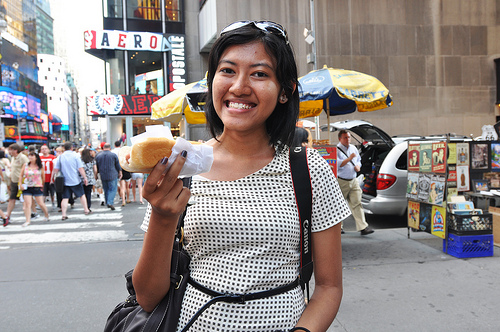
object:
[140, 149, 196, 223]
hand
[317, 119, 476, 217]
car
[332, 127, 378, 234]
man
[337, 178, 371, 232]
pants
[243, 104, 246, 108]
teeth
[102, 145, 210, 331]
purse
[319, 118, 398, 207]
hatchback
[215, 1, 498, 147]
wall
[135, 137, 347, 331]
dress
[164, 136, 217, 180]
paper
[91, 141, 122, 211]
people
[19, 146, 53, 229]
woman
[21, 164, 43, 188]
sleeveless top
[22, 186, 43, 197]
shorts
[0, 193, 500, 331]
road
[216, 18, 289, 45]
sunglasses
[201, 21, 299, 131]
head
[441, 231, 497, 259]
carton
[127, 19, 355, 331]
woman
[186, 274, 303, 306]
belt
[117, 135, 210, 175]
hotdog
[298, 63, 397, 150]
umbrella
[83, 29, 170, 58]
sign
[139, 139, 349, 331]
pattern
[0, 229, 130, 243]
stripes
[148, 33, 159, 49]
letters